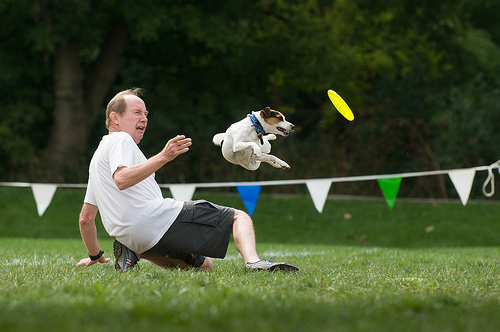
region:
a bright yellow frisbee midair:
[310, 79, 368, 133]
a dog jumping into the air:
[207, 104, 321, 186]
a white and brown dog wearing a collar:
[206, 99, 300, 184]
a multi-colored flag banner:
[175, 144, 497, 216]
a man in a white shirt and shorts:
[78, 87, 245, 279]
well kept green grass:
[298, 223, 491, 313]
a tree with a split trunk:
[15, 17, 137, 182]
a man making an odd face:
[75, 81, 180, 193]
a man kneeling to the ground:
[85, 109, 263, 284]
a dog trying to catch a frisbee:
[190, 87, 420, 194]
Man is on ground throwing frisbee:
[67, 77, 387, 277]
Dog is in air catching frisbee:
[207, 70, 369, 187]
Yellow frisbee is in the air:
[305, 58, 396, 144]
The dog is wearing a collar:
[206, 92, 296, 177]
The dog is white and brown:
[201, 95, 301, 188]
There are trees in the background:
[30, 9, 474, 84]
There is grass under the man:
[35, 279, 479, 321]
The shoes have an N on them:
[110, 230, 143, 278]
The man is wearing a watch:
[72, 237, 111, 277]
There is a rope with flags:
[261, 161, 498, 224]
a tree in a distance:
[353, 40, 392, 122]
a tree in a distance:
[168, 72, 210, 147]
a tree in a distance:
[44, 70, 91, 158]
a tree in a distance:
[434, 92, 471, 182]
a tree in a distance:
[7, 97, 35, 180]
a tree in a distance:
[363, 9, 428, 72]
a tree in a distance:
[433, 42, 480, 162]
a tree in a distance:
[15, 9, 97, 67]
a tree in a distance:
[164, 20, 276, 69]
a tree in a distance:
[300, 18, 390, 74]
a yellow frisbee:
[305, 77, 375, 154]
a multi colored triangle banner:
[13, 167, 498, 227]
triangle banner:
[29, 159, 494, 219]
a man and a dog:
[64, 67, 355, 244]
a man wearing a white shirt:
[66, 75, 211, 256]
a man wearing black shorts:
[55, 82, 261, 264]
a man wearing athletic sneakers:
[62, 81, 318, 318]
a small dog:
[206, 80, 330, 190]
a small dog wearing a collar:
[186, 67, 311, 191]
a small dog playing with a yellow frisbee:
[188, 50, 408, 222]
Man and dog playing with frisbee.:
[44, 33, 452, 310]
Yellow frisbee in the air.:
[313, 65, 362, 139]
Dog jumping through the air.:
[194, 77, 311, 184]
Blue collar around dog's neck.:
[223, 100, 291, 144]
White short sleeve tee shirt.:
[77, 117, 186, 259]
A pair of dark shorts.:
[146, 186, 244, 276]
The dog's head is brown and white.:
[248, 96, 305, 141]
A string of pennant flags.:
[1, 167, 488, 206]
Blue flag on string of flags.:
[228, 175, 278, 223]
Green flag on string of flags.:
[368, 160, 412, 213]